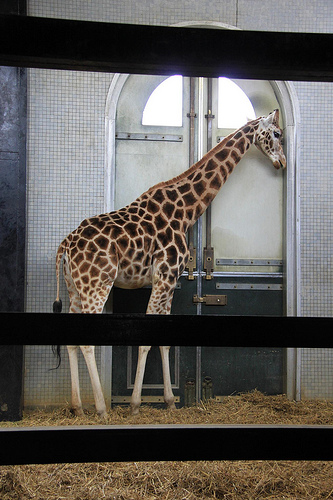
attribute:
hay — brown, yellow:
[2, 390, 333, 495]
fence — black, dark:
[3, 10, 332, 466]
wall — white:
[25, 3, 333, 405]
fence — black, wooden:
[10, 305, 327, 464]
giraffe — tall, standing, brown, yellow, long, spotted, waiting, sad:
[45, 102, 290, 413]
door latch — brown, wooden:
[190, 288, 234, 307]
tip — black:
[45, 296, 63, 370]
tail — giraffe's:
[45, 236, 68, 365]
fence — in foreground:
[23, 303, 326, 474]